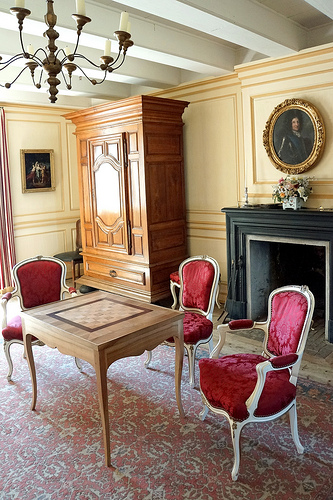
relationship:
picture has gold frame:
[256, 94, 333, 177] [282, 94, 309, 110]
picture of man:
[256, 94, 333, 177] [283, 116, 306, 157]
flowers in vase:
[280, 186, 301, 194] [283, 200, 303, 211]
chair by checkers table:
[15, 264, 65, 335] [26, 304, 179, 436]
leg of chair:
[269, 399, 312, 462] [15, 264, 65, 335]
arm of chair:
[259, 343, 299, 378] [15, 264, 65, 335]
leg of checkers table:
[269, 399, 312, 462] [26, 304, 179, 436]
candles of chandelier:
[71, 14, 140, 42] [12, 10, 122, 76]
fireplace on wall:
[225, 207, 328, 323] [213, 167, 257, 199]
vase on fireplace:
[283, 200, 303, 211] [225, 207, 328, 323]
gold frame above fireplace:
[282, 94, 309, 110] [225, 207, 328, 323]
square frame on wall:
[13, 138, 71, 200] [35, 118, 51, 132]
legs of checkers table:
[19, 340, 201, 460] [26, 304, 179, 436]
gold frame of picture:
[282, 94, 309, 110] [256, 94, 333, 177]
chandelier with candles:
[12, 10, 122, 76] [71, 14, 140, 42]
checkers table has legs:
[26, 304, 179, 436] [19, 340, 201, 460]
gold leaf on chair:
[222, 417, 251, 444] [15, 264, 65, 335]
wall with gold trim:
[213, 167, 257, 199] [47, 214, 92, 225]